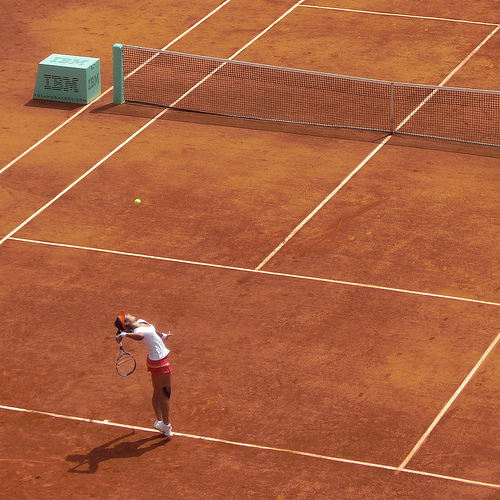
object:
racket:
[115, 342, 137, 378]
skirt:
[146, 354, 174, 376]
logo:
[43, 73, 80, 93]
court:
[1, 0, 498, 497]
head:
[114, 313, 135, 331]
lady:
[113, 309, 175, 438]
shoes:
[157, 421, 173, 437]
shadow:
[63, 428, 168, 476]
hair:
[114, 316, 133, 335]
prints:
[397, 310, 457, 387]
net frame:
[112, 43, 125, 105]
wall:
[163, 137, 296, 203]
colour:
[235, 302, 388, 413]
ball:
[135, 198, 141, 204]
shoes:
[152, 419, 162, 429]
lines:
[0, 406, 500, 489]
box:
[33, 52, 102, 105]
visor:
[117, 308, 128, 328]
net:
[119, 44, 499, 147]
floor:
[240, 308, 420, 418]